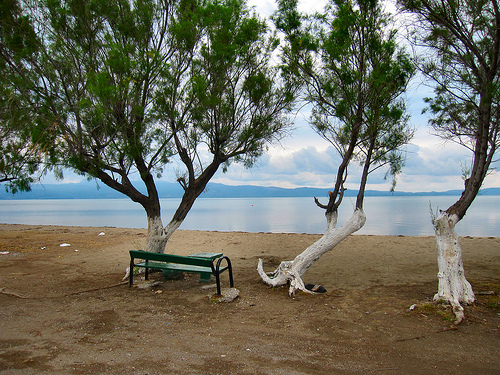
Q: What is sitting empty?
A: A park bench.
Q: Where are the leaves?
A: The leaves are on the various trees.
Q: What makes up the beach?
A: Dirt and sand make up the beach.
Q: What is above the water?
A: Cloudy skies are above the water.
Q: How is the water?
A: The water is smooth.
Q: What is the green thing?
A: A bench.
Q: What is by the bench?
A: Trees.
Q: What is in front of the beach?
A: Water.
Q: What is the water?
A: A lake.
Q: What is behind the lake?
A: Mountains.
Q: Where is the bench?
A: By the trees.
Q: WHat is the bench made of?
A: Metal.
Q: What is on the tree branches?
A: Leaves.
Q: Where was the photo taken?
A: On the beach.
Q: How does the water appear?
A: Calm.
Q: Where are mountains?
A: In the far distance.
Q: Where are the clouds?
A: In the sky.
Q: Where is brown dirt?
A: On the ground.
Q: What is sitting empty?
A: The bench.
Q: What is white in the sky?
A: Clouds.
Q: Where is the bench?
A: Next to a tree.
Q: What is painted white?
A: Trees.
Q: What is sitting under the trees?
A: Bench.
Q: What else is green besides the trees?
A: Bench.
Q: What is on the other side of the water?
A: Mountains.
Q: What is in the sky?
A: Clouds.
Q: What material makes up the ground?
A: Sand.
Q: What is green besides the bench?
A: Trees.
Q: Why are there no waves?
A: It is a lake.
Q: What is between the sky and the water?
A: Mountains.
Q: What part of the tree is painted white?
A: Trunk.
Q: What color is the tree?
A: White.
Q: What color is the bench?
A: Green.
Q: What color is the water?
A: Blue.